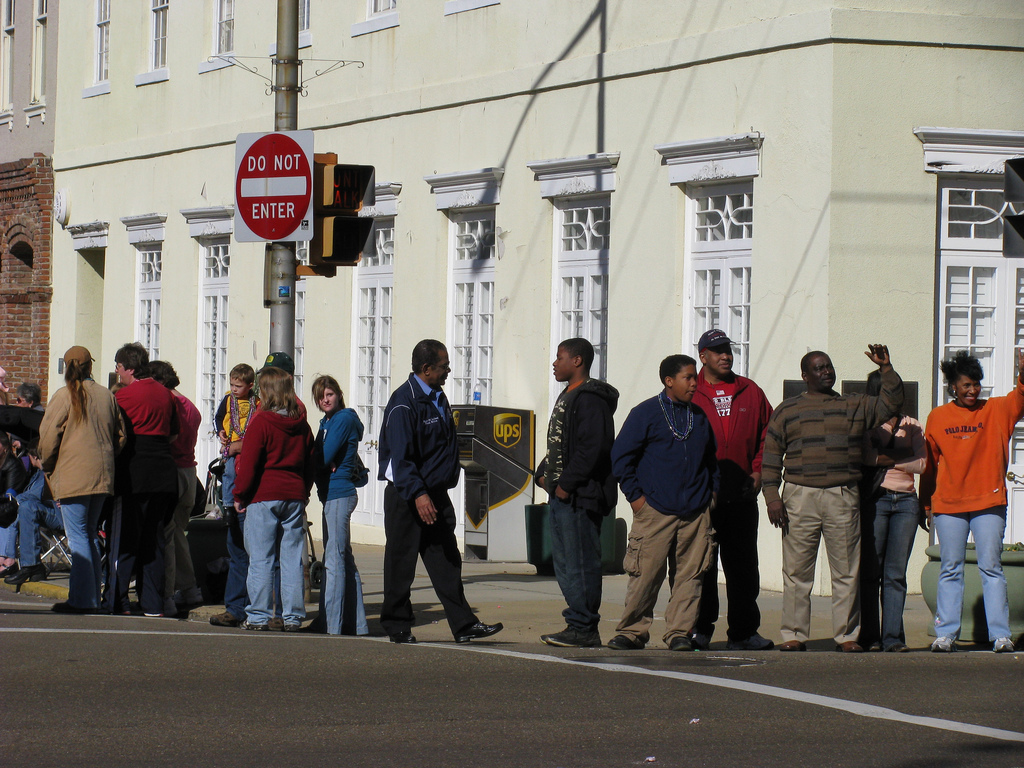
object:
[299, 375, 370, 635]
girl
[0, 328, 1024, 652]
people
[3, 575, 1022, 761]
street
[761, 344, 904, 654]
man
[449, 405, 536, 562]
box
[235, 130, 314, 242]
sign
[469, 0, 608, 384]
shadow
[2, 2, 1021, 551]
wall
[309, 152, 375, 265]
light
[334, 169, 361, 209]
directions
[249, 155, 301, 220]
warning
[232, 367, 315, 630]
woman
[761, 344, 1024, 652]
two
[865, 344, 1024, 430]
waving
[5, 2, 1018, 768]
weather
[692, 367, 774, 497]
jacket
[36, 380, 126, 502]
jacket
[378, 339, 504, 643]
man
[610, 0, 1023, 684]
right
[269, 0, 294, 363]
pole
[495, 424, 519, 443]
ups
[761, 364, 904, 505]
sweather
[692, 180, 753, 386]
windows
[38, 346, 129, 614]
woman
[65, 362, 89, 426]
ponytail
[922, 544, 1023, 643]
pot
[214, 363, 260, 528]
child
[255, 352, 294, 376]
man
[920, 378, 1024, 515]
sweater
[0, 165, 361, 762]
left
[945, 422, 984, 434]
letters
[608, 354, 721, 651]
man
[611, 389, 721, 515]
blue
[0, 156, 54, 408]
building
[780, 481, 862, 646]
pants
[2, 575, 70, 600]
paint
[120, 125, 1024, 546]
windows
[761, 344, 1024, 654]
people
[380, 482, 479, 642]
pants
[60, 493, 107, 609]
jeans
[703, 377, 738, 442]
shirt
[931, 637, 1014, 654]
shoes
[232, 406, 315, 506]
hoodie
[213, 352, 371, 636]
people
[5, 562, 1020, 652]
curb